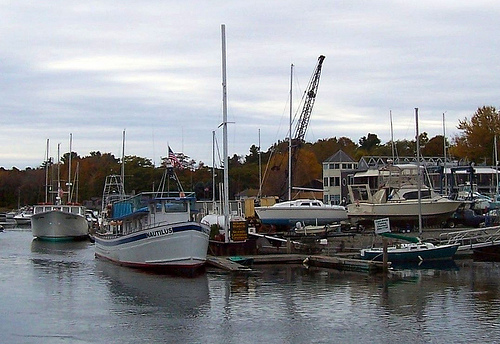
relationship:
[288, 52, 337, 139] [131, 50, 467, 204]
crane in background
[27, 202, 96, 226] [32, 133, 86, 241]
windows on boat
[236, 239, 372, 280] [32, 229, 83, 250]
dock by boat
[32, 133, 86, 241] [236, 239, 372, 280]
boat on dock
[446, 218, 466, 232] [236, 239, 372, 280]
wheels on dock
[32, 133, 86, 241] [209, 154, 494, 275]
boat at dock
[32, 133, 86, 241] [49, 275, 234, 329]
boat in water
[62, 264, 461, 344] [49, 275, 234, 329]
body of water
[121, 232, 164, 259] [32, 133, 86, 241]
side of boat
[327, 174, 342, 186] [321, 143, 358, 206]
window on outside of building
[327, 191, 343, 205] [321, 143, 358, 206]
window on outside of building